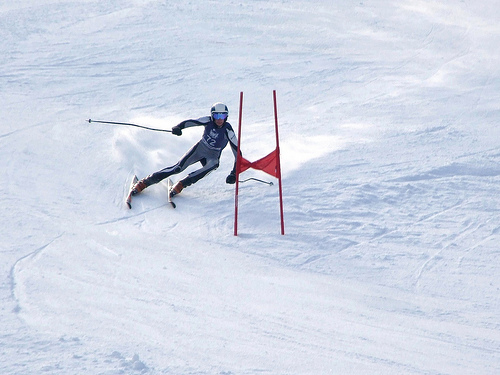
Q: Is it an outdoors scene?
A: Yes, it is outdoors.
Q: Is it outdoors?
A: Yes, it is outdoors.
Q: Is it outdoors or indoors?
A: It is outdoors.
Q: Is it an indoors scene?
A: No, it is outdoors.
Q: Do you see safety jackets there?
A: No, there are no safety jackets.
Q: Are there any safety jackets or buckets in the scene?
A: No, there are no safety jackets or buckets.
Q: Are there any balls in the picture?
A: No, there are no balls.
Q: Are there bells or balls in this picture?
A: No, there are no balls or bells.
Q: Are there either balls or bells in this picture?
A: No, there are no balls or bells.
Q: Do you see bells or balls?
A: No, there are no balls or bells.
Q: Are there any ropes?
A: No, there are no ropes.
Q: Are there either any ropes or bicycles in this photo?
A: No, there are no ropes or bicycles.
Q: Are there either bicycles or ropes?
A: No, there are no ropes or bicycles.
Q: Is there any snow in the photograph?
A: Yes, there is snow.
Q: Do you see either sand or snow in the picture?
A: Yes, there is snow.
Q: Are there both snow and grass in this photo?
A: No, there is snow but no grass.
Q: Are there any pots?
A: No, there are no pots.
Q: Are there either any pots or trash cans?
A: No, there are no pots or trash cans.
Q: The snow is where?
A: The snow is on the ground.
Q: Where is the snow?
A: The snow is on the ground.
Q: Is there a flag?
A: Yes, there is a flag.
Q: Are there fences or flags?
A: Yes, there is a flag.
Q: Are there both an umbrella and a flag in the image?
A: No, there is a flag but no umbrellas.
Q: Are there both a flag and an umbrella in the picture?
A: No, there is a flag but no umbrellas.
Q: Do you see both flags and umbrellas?
A: No, there is a flag but no umbrellas.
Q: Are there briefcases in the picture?
A: No, there are no briefcases.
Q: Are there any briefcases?
A: No, there are no briefcases.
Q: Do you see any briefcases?
A: No, there are no briefcases.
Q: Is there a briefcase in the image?
A: No, there are no briefcases.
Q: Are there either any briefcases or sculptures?
A: No, there are no briefcases or sculptures.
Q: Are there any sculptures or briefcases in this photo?
A: No, there are no briefcases or sculptures.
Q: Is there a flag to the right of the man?
A: Yes, there is a flag to the right of the man.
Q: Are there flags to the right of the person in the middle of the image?
A: Yes, there is a flag to the right of the man.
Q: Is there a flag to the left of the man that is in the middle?
A: No, the flag is to the right of the man.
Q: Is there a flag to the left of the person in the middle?
A: No, the flag is to the right of the man.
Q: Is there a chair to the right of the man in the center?
A: No, there is a flag to the right of the man.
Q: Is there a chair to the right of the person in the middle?
A: No, there is a flag to the right of the man.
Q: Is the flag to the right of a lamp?
A: No, the flag is to the right of the man.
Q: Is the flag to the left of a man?
A: No, the flag is to the right of a man.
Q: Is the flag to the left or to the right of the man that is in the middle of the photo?
A: The flag is to the right of the man.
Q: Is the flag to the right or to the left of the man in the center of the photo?
A: The flag is to the right of the man.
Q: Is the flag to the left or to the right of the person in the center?
A: The flag is to the right of the man.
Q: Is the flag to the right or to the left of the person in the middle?
A: The flag is to the right of the man.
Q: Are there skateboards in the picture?
A: No, there are no skateboards.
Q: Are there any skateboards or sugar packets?
A: No, there are no skateboards or sugar packets.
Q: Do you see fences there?
A: No, there are no fences.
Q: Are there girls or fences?
A: No, there are no fences or girls.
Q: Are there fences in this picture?
A: No, there are no fences.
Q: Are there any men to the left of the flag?
A: Yes, there is a man to the left of the flag.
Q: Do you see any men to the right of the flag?
A: No, the man is to the left of the flag.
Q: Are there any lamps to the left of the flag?
A: No, there is a man to the left of the flag.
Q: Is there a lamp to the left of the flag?
A: No, there is a man to the left of the flag.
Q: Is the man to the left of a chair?
A: No, the man is to the left of the flag.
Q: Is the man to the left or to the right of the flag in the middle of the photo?
A: The man is to the left of the flag.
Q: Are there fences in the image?
A: No, there are no fences.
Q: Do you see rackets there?
A: No, there are no rackets.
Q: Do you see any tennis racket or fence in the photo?
A: No, there are no rackets or fences.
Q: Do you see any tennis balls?
A: No, there are no tennis balls.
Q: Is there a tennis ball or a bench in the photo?
A: No, there are no tennis balls or benches.